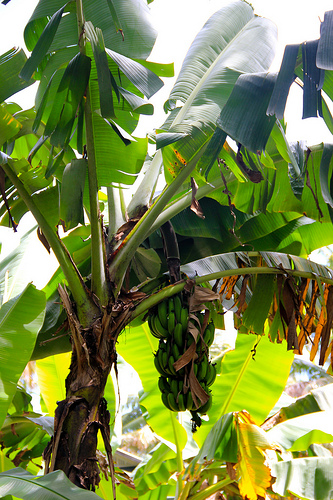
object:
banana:
[154, 313, 169, 338]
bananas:
[168, 311, 176, 333]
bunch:
[168, 354, 176, 372]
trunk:
[52, 333, 113, 488]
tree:
[0, 0, 332, 499]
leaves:
[186, 265, 333, 373]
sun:
[163, 1, 246, 82]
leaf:
[19, 0, 174, 230]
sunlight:
[174, 19, 240, 86]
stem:
[74, 0, 106, 305]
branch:
[107, 182, 173, 283]